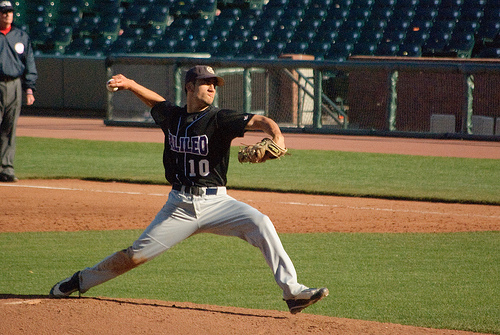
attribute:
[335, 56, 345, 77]
chair — blue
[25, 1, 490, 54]
stadium seats — blue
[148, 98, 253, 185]
baseball jersey — black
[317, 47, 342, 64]
chair — blue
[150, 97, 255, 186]
shirt — black